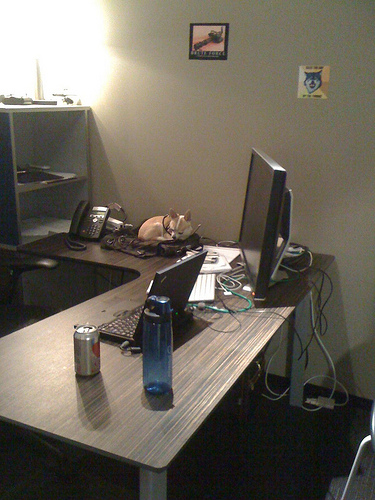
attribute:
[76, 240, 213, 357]
laptop — black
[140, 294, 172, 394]
bottle — plastic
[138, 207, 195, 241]
dog — small, curled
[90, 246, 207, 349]
laptop — small, black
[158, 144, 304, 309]
computer — messy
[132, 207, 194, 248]
dog — figurine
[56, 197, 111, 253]
phone — black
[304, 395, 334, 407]
keyboard — tan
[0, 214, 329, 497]
table — wood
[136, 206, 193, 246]
dog — small, curled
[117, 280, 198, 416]
bottle. — blue, empty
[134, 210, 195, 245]
dog — small, curled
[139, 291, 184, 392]
bottle — blue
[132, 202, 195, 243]
dog — small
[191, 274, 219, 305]
keyboard — white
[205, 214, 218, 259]
dog desk — curled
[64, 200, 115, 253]
phone — black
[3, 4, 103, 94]
sunlight — shining